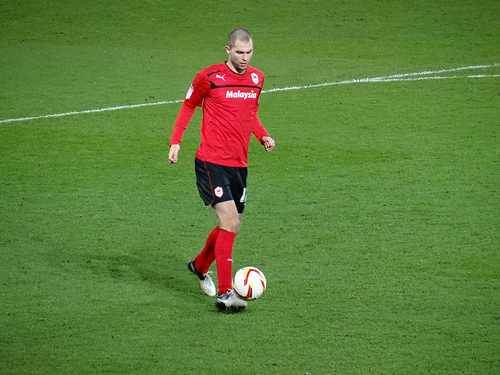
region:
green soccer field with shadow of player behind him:
[4, 3, 494, 369]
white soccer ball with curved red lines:
[232, 266, 269, 301]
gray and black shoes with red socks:
[186, 224, 249, 314]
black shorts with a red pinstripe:
[193, 156, 250, 213]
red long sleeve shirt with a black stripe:
[168, 61, 270, 166]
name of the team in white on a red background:
[222, 87, 257, 105]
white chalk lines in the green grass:
[0, 58, 495, 129]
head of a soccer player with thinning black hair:
[223, 25, 255, 74]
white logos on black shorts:
[213, 181, 252, 207]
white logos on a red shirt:
[209, 70, 261, 88]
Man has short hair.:
[226, 23, 256, 49]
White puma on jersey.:
[212, 71, 232, 86]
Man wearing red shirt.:
[198, 65, 268, 169]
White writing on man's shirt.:
[217, 86, 260, 103]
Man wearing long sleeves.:
[155, 93, 224, 176]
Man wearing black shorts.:
[196, 168, 259, 195]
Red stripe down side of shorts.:
[194, 153, 220, 209]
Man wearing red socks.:
[188, 226, 258, 279]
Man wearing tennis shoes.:
[187, 270, 267, 335]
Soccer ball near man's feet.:
[232, 258, 284, 308]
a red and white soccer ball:
[230, 258, 265, 298]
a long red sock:
[216, 225, 236, 290]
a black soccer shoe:
[211, 291, 243, 306]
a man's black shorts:
[191, 155, 246, 212]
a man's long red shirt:
[170, 62, 270, 172]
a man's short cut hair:
[225, 25, 252, 46]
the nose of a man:
[237, 50, 247, 60]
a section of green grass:
[310, 168, 486, 283]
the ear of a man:
[223, 43, 230, 53]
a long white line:
[258, 54, 495, 99]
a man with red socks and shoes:
[176, 219, 287, 316]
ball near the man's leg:
[197, 261, 283, 318]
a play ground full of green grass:
[333, 104, 482, 359]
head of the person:
[219, 28, 262, 68]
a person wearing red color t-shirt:
[161, 65, 287, 171]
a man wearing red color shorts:
[183, 152, 261, 220]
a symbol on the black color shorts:
[207, 182, 228, 199]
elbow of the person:
[168, 85, 201, 121]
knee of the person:
[201, 202, 246, 239]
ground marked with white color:
[335, 33, 467, 137]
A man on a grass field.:
[161, 28, 281, 320]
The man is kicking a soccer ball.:
[164, 20, 288, 319]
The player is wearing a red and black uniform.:
[169, 26, 280, 318]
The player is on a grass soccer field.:
[168, 18, 286, 320]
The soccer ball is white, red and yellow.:
[232, 262, 269, 304]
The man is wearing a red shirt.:
[172, 18, 290, 320]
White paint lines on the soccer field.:
[3, 53, 496, 132]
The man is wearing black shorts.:
[164, 23, 285, 314]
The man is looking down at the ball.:
[161, 28, 298, 325]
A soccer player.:
[157, 14, 319, 314]